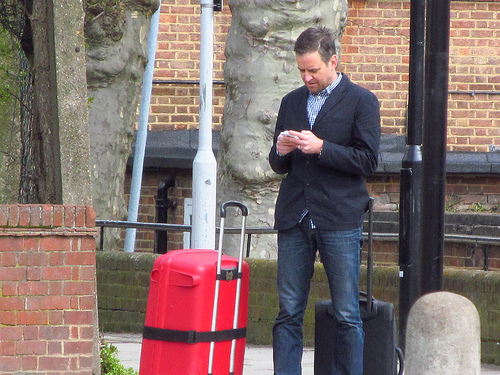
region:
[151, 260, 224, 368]
The suit case is red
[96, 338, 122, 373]
The weeds are green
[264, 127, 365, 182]
The man's hands are together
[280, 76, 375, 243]
The man has a suit jacket on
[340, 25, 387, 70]
The building is brick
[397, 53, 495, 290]
The pole is black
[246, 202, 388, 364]
The man has blue jeans on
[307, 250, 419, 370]
A suitcase is in the back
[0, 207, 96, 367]
bricks on the building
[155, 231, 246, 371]
a red suitcase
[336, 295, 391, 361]
a black suitcase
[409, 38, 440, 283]
a black pole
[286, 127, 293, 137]
a cell phone in the mans hands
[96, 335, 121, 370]
leaves on the ground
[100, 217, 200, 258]
a railing on the wall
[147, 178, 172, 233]
a black pole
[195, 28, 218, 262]
a white pole behind the suitcase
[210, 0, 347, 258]
part of a large gray sculpture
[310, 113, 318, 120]
a white button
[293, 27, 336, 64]
a man's short cut hair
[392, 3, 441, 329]
a long black pole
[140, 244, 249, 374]
a large red suitcase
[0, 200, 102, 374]
part of a brick wall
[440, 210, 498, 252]
part of a black bench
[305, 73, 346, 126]
a man's collared blue shirt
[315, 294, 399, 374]
a black suitcase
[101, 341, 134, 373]
green tree leaves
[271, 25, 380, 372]
a man standing between two suitcases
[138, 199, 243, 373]
a red suicase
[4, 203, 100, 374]
a small brick wall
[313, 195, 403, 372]
a small black suitcase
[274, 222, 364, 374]
man wearing blue jeans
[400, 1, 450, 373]
a black metal pole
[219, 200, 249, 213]
black handle of a suitcase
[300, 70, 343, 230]
man wearing a blue and white stripe button-down shirt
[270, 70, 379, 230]
man wearing a blue jacket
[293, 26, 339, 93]
man with short brown hair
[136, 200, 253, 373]
Red plastic suitcase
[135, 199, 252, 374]
Red suitcase with a metal handle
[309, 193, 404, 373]
Black suitcase with a black expandable handle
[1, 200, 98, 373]
Red bricks on a building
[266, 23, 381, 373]
Man holding a cellphone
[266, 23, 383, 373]
Man texting on a cellphone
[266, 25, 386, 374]
Man wearing a blue jacket and striped shirt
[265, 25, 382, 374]
Man wearing blue jeans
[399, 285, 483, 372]
Circular cement object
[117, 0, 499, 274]
Brown brick building